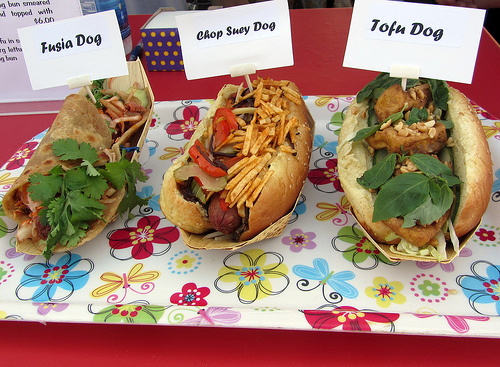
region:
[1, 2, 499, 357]
hot dogs on tray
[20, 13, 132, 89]
signs says Fusia Dog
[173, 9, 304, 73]
sign says Chop Suey Dog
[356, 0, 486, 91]
sign says Tofu Dog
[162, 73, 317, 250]
french fries on hot dot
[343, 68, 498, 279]
tofu dog on bun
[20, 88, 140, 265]
hot dog rolled in tortilla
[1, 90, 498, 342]
three hot dogs on flowered tray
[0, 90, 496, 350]
tray has yellow, blue and purple flowers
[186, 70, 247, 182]
tomatoes on hot dog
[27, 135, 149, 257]
Bunch of cilantro on top of hot dog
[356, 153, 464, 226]
Basil leaves on top of hot dog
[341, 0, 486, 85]
White sign with black lettering on hot dog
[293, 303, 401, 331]
Red and black flower on placemat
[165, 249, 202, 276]
Yellow flower image with blue dots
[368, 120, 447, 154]
Marinated and cooked tofu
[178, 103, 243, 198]
Fresh vegetables on top of hot dog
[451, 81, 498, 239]
Sesame seeds on side of bun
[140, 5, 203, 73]
Purple box with yellow dots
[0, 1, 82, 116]
Menu sitting on table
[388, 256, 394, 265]
part of a board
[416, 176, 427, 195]
part of a vegetable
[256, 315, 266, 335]
edge of a table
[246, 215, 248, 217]
part of a bread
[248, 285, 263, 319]
part of a cloth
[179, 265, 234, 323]
edge of a cloth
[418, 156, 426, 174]
part of a leaf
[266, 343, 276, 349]
edge of a door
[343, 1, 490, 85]
Tofu sign for serving tray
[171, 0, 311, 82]
Chop Suey Dog sign for serving tray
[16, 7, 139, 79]
Fugia dog sign for serving tray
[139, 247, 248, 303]
Part of floral serving tray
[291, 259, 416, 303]
Part of floral serving tray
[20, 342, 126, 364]
Decorative Red serving table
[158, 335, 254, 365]
Part of red serving table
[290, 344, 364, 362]
part of red serving table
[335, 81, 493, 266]
Delicious stuffed Tofu dog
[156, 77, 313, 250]
Delicious chop suey dog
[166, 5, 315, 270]
A chop suey hot dog.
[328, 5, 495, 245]
A tofu hot dog.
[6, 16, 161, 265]
A Fusia hot dog.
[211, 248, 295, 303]
A yellow flower on the table cloth.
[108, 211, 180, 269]
A red flower on the table cloth.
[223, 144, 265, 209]
Yellow potatoes on the hot dog.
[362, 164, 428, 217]
A green leaf of basil.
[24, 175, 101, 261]
A large parsley leaf.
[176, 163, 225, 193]
A large cream colored piece of food.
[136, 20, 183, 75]
A blue polka dot design on a box.